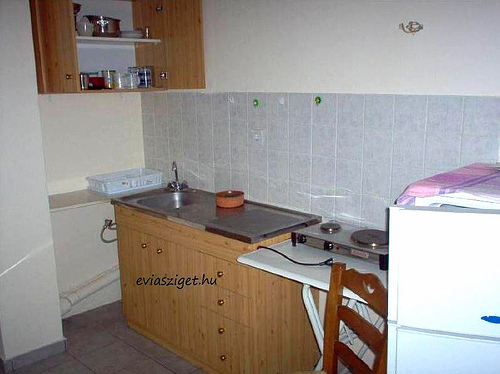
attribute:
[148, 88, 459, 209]
backsplash — gray, tile, tiled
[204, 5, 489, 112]
wall — white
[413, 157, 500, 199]
blanket — pink, purple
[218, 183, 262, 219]
bowl — orange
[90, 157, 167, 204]
bin — white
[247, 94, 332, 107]
magnets — green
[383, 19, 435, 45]
hook — silver, hanging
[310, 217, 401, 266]
burner — silver, for cooking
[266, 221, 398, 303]
table — white, folding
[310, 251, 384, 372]
chair — wooden, brown, wood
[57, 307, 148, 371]
tile — brown, grey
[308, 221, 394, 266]
hot plate — electrical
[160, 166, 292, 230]
faucet — diagonal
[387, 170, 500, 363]
refrigerator — white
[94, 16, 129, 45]
pot — medium sized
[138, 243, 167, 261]
drawer pulls — bronze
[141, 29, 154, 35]
glasses — for drinking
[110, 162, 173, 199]
dish drainer — white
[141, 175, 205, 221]
sink — metal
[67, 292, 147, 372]
floor — tiled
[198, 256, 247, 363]
drawers — stacked up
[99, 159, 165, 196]
basket — white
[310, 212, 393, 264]
portable stove — silver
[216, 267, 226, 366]
knobs — copper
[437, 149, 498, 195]
towel — laid out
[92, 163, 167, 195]
dish rack — white, plastic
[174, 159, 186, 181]
spout — silver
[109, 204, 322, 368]
cabinets — wood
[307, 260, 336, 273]
plug — black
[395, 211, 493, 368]
door — open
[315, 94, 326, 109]
circle — green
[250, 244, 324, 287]
cord — black, electrical